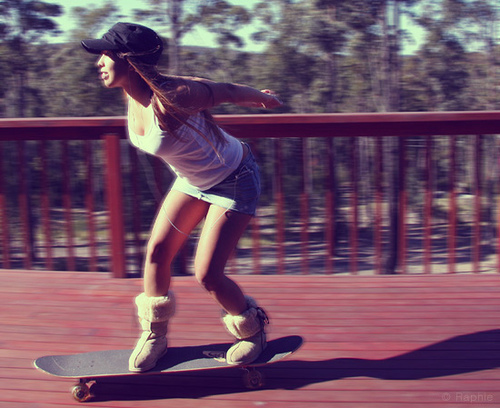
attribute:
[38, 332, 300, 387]
skateboard — grey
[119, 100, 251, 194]
tank top — white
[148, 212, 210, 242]
wire — white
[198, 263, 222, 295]
knee — bare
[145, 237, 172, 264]
knee — bare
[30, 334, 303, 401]
skateboard — black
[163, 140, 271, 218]
skirt — mini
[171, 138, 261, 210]
skirt — blue jean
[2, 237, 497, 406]
floor — red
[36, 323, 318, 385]
longboard — black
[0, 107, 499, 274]
fence — brown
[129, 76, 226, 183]
top — white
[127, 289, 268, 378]
boots — furry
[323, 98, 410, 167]
post — wooden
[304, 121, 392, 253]
post — wooden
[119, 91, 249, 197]
shirt — white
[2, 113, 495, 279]
railing — red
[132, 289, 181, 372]
boot — furry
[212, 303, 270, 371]
boot — furry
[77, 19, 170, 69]
hat — black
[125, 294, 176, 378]
boot — light brown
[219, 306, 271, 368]
boot — light brown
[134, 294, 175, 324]
trim — fur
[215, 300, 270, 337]
trim — fur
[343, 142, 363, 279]
post — wooden